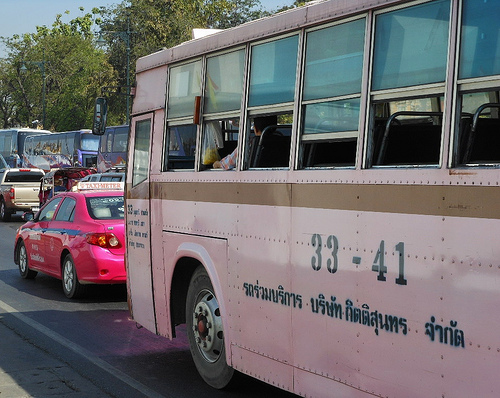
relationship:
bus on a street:
[124, 0, 498, 395] [4, 200, 280, 397]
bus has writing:
[124, 0, 498, 395] [238, 230, 467, 356]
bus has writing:
[124, 0, 498, 395] [126, 199, 152, 258]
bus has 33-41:
[124, 0, 498, 395] [305, 231, 412, 284]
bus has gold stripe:
[124, 0, 498, 395] [124, 178, 499, 225]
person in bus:
[215, 112, 277, 173] [124, 0, 498, 395]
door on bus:
[124, 109, 161, 337] [124, 0, 498, 395]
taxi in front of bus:
[15, 182, 129, 300] [124, 0, 498, 395]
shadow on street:
[1, 308, 287, 393] [4, 200, 280, 397]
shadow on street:
[3, 262, 124, 304] [4, 200, 280, 397]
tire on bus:
[181, 260, 242, 387] [124, 0, 498, 395]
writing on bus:
[238, 230, 467, 356] [124, 0, 498, 395]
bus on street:
[124, 0, 498, 395] [4, 200, 280, 397]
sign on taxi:
[77, 180, 125, 191] [15, 182, 129, 300]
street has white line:
[4, 200, 280, 397] [3, 296, 168, 396]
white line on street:
[3, 296, 168, 396] [4, 200, 280, 397]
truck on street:
[3, 168, 40, 219] [4, 200, 280, 397]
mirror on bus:
[93, 91, 114, 145] [124, 0, 498, 395]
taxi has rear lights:
[15, 182, 129, 300] [87, 231, 118, 250]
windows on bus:
[168, 1, 499, 168] [124, 0, 498, 395]